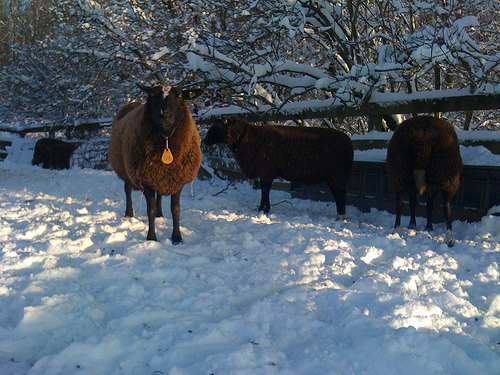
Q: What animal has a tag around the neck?
A: A sheep.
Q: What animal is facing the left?
A: A sheep.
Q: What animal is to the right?
A: A sheep.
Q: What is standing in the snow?
A: A sheep.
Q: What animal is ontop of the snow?
A: A sheep.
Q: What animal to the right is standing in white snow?
A: A sheep.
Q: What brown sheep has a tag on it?
A: The left one.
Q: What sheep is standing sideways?
A: The middle one.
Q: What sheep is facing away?
A: One on the right.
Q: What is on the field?
A: Snow.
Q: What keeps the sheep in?
A: The fence.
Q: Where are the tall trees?
A: Behind the fence.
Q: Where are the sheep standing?
A: In the snow.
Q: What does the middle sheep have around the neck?
A: Collar.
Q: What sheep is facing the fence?
A: Far right one.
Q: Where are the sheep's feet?
A: In the snow.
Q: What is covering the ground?
A: Snow.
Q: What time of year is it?
A: Winter.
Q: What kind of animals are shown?
A: Sheep.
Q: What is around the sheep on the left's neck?
A: A tag.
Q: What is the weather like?
A: Cold.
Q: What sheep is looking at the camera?
A: The one on the left.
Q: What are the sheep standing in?
A: Snow.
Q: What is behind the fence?
A: Trees.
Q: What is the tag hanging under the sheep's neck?
A: It is an identification tag.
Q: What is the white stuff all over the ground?
A: It is dirty snow.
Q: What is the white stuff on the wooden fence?
A: It is freshly fallen snow.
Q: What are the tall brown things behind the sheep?
A: They are trees with long branches.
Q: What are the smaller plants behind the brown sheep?
A: They are bushes covered in snow.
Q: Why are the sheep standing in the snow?
A: So that can eat food and walk around.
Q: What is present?
A: Animals.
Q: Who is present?
A: Nobody.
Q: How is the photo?
A: Clear.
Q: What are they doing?
A: Standing.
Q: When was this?
A: Daytime.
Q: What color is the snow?
A: White.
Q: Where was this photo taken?
A: In the sheep pasture.